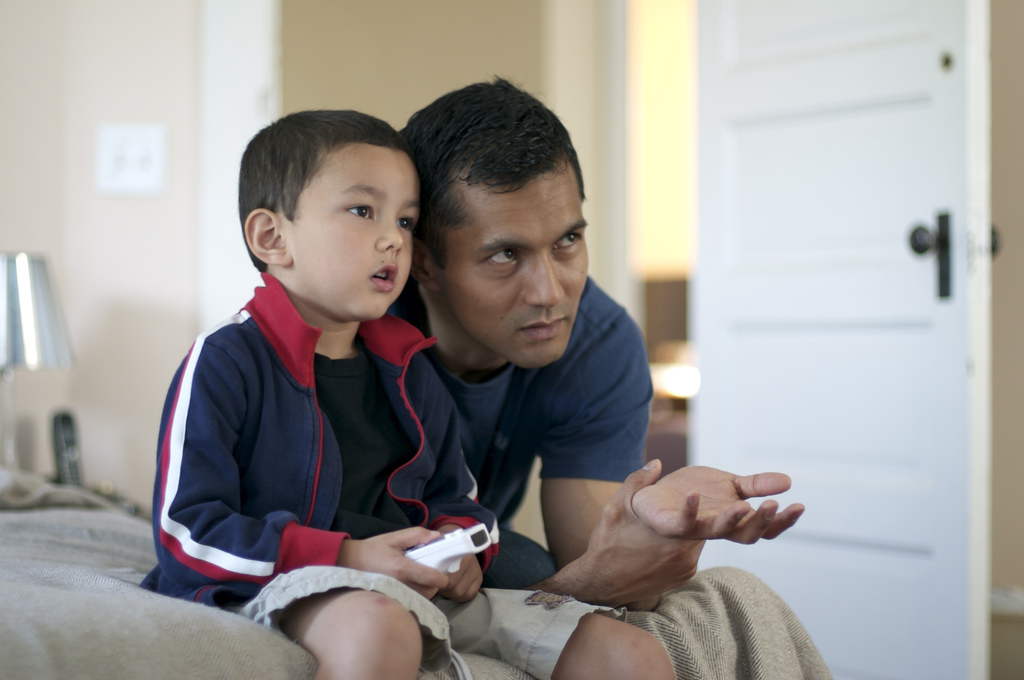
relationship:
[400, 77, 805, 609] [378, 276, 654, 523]
dad in blue shirt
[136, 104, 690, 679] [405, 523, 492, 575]
boy holding controller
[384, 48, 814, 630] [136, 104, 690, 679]
dad next to boy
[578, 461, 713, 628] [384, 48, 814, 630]
hands on dad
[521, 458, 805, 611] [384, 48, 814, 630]
hands on dad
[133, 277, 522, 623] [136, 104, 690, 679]
jacket on boy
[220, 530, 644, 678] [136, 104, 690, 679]
shorts on boy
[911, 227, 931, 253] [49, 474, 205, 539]
black-door knob on table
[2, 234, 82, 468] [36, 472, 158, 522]
lamp on table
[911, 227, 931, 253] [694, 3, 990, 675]
black-door knob on door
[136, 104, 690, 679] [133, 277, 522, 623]
boy wearing jacket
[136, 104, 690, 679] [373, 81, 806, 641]
boy with man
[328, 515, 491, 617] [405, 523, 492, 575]
boy's hands holding controller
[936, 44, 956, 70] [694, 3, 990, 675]
black spot on door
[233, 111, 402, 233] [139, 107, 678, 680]
hair on boy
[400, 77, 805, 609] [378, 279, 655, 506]
dad has a blue shirt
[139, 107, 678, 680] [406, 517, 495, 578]
boy holding controller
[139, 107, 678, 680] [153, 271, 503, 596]
boy wearing jacket